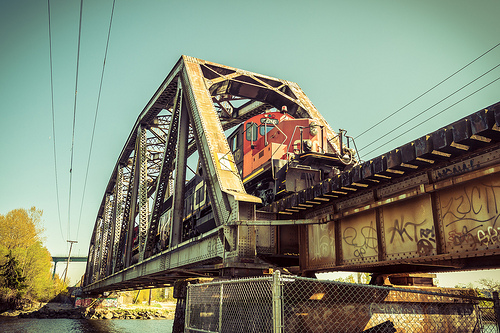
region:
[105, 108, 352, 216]
a train on a bridge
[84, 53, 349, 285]
a large metal bridge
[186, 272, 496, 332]
a metal chain link fence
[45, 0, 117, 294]
a section of power lines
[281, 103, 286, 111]
light on top of a train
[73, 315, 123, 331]
a shadow on water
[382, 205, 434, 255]
graffiti on metal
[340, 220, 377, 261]
graffiti on a metal plate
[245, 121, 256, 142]
window on a train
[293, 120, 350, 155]
metal rail on a train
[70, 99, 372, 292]
a train on the tracks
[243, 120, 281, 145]
the windshield of the train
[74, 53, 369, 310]
a metal train bridge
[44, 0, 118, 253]
black power lines in the air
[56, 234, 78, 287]
a wooden telephone pole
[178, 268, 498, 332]
a gray chain link fence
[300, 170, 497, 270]
graffiti on the bridge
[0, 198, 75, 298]
a green tree next to the water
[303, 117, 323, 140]
the headlight of the train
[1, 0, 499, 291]
a clear blue sky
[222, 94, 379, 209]
train on bridge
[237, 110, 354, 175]
red train car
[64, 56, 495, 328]
bridge over water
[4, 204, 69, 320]
trees next to long train track over bridge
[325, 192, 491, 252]
graffiti on bridge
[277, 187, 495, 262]
bridge has been vandalized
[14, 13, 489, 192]
blue sky over power lines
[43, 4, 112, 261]
power lines over water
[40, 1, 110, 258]
electrical lines over water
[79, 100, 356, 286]
train passing over bridge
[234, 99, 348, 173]
red train on bridge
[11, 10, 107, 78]
white cloud in blue sky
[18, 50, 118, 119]
white cloud in blue sky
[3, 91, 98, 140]
white cloud in blue sky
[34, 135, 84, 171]
white cloud in blue sky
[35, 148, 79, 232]
white cloud in blue sky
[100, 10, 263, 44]
white cloud in blue sky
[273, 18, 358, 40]
white cloud in blue sky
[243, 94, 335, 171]
red train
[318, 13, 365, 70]
white cloud in blue sky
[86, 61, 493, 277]
a train on a track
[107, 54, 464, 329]
a train on a bridge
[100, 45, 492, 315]
train tracks over the water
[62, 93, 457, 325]
train tracks on a bridge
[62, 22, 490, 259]
a train over the water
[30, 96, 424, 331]
a bridge going across the water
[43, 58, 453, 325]
a train bridge over the water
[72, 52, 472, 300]
a bridge that carries trains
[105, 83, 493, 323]
a train moving on a bridge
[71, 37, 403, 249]
a train moving above the water